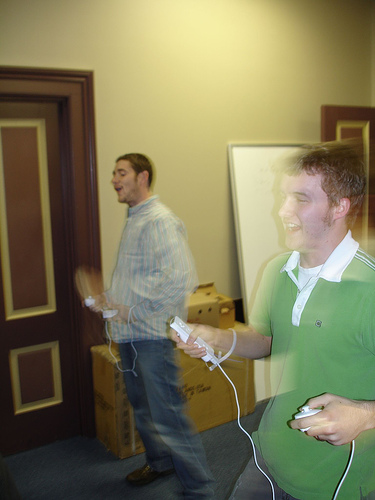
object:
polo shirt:
[250, 229, 375, 500]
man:
[166, 145, 374, 498]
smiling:
[283, 220, 302, 235]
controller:
[295, 405, 323, 433]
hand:
[287, 392, 375, 446]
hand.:
[171, 323, 216, 358]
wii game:
[75, 287, 356, 496]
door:
[0, 66, 105, 459]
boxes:
[89, 318, 255, 458]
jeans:
[118, 339, 216, 500]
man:
[82, 153, 219, 500]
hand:
[107, 303, 133, 325]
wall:
[118, 0, 310, 135]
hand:
[81, 294, 106, 313]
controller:
[102, 309, 118, 318]